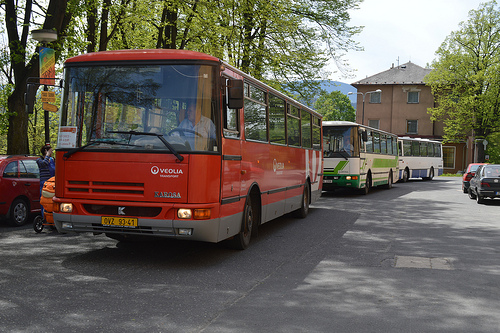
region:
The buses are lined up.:
[54, 50, 445, 255]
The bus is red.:
[185, 160, 213, 200]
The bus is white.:
[400, 160, 441, 168]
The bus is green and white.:
[325, 159, 357, 174]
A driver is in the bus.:
[179, 100, 212, 135]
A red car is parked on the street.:
[0, 154, 35, 226]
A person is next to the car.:
[34, 142, 58, 179]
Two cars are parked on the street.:
[462, 162, 498, 201]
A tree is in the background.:
[431, 1, 498, 138]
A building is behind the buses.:
[353, 60, 426, 120]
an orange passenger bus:
[54, 55, 325, 242]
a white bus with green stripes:
[319, 120, 401, 187]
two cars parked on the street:
[462, 160, 499, 207]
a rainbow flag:
[41, 47, 53, 86]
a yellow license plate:
[99, 215, 138, 228]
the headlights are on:
[58, 199, 191, 216]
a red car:
[0, 156, 44, 217]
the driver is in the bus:
[173, 104, 217, 144]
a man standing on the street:
[35, 141, 59, 232]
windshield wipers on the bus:
[60, 128, 182, 160]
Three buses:
[56, 40, 455, 242]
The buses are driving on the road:
[45, 39, 459, 254]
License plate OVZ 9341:
[80, 208, 154, 233]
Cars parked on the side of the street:
[457, 148, 498, 214]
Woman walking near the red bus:
[21, 135, 56, 194]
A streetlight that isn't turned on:
[21, 20, 65, 152]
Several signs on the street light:
[36, 46, 61, 118]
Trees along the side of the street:
[11, 7, 293, 65]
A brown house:
[352, 60, 467, 147]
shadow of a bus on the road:
[58, 207, 361, 292]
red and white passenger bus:
[53, 46, 324, 250]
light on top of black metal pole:
[30, 27, 59, 144]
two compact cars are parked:
[459, 161, 498, 205]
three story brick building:
[350, 60, 474, 176]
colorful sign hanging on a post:
[38, 47, 57, 86]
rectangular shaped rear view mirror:
[225, 77, 245, 109]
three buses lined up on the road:
[51, 50, 443, 251]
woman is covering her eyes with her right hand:
[35, 143, 57, 220]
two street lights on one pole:
[346, 89, 383, 123]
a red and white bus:
[45, 47, 325, 244]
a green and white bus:
[323, 116, 395, 188]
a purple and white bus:
[402, 138, 445, 180]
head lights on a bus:
[58, 201, 194, 219]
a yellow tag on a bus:
[97, 216, 141, 228]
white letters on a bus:
[150, 163, 183, 175]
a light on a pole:
[31, 23, 56, 142]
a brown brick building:
[361, 62, 447, 129]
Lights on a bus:
[173, 204, 212, 224]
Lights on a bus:
[48, 197, 75, 217]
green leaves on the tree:
[433, 76, 458, 111]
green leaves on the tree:
[477, 24, 489, 67]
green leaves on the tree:
[258, 42, 308, 76]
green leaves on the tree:
[172, 11, 225, 55]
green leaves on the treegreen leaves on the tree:
[315, 12, 357, 64]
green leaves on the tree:
[332, 79, 349, 103]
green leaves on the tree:
[315, 91, 357, 126]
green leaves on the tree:
[27, 110, 53, 152]